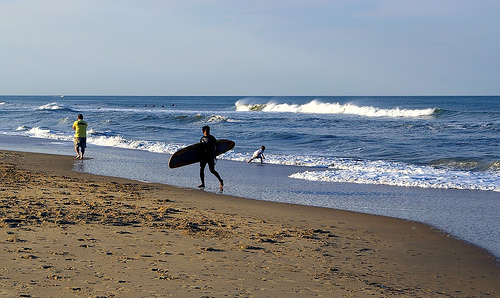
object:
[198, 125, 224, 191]
man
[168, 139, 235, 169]
board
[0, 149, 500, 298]
sand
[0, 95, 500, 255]
water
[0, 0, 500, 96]
sky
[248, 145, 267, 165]
child